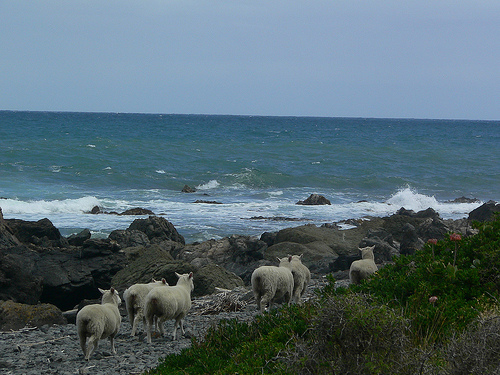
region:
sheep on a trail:
[63, 241, 386, 361]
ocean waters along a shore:
[26, 117, 496, 192]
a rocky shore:
[44, 218, 258, 274]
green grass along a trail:
[270, 316, 388, 353]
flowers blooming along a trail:
[418, 222, 474, 314]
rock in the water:
[175, 182, 200, 197]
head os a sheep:
[92, 285, 125, 305]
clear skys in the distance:
[24, 10, 466, 102]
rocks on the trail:
[8, 329, 58, 369]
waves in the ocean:
[11, 189, 96, 214]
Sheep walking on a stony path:
[69, 242, 379, 360]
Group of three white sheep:
[77, 271, 198, 362]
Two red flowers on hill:
[422, 232, 466, 268]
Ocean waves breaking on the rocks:
[19, 163, 459, 230]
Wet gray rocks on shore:
[4, 214, 122, 305]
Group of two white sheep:
[249, 251, 314, 313]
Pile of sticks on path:
[205, 287, 247, 317]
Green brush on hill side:
[300, 292, 492, 368]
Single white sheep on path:
[344, 242, 385, 285]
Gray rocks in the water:
[86, 203, 153, 216]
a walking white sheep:
[72, 285, 123, 360]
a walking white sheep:
[143, 269, 195, 341]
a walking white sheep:
[123, 276, 170, 336]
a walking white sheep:
[249, 255, 293, 312]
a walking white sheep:
[285, 252, 310, 301]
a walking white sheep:
[348, 243, 380, 288]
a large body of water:
[2, 112, 497, 234]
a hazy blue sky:
[0, 0, 499, 123]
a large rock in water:
[297, 192, 327, 206]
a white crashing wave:
[385, 185, 481, 215]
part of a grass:
[356, 331, 380, 363]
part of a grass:
[340, 284, 381, 364]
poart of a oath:
[103, 297, 145, 359]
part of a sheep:
[151, 298, 171, 329]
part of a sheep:
[157, 278, 200, 338]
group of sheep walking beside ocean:
[60, 246, 420, 373]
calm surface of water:
[79, 112, 347, 139]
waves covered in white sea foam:
[44, 196, 78, 213]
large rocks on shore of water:
[21, 223, 149, 280]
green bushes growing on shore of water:
[409, 251, 487, 313]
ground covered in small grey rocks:
[14, 330, 71, 371]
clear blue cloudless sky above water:
[259, 2, 497, 114]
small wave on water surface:
[206, 159, 278, 197]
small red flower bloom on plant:
[444, 228, 469, 248]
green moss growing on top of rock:
[3, 298, 58, 322]